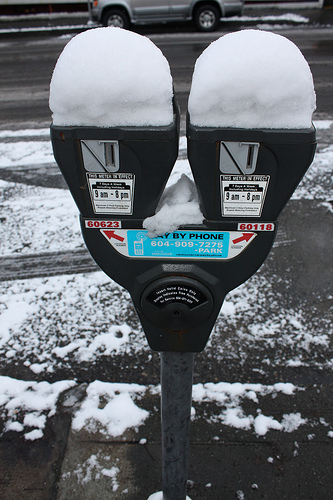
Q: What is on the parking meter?
A: Snow.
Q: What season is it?
A: Winter.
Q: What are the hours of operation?
A: 9 am - 8 pm.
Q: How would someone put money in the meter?
A: Through the coin slots.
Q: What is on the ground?
A: Snow.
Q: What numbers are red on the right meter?
A: 60118.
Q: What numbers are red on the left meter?
A: 60623.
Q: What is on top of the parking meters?
A: Snow.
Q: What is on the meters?
A: Snow.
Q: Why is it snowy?
A: It is winter.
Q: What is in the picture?
A: Two meters.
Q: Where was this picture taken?
A: The street.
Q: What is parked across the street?
A: A car.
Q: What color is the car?
A: Silver.